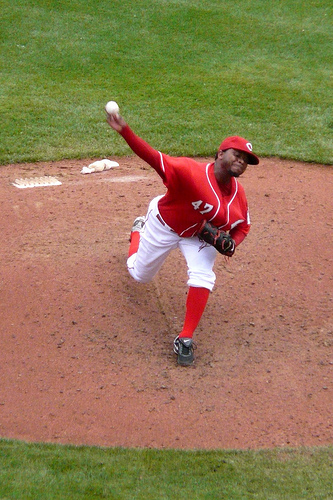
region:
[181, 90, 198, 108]
part of a grass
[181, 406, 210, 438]
part of a ground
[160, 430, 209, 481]
edge of a field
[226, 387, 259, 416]
part of a ground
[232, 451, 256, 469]
part of a fiedl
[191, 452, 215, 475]
part of a field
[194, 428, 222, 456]
part of a ground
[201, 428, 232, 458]
edge of a field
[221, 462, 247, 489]
part of a field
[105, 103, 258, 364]
A baseball player throwing a ball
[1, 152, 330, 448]
A pitcher's mound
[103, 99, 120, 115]
A baseball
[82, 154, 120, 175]
Some bags on the ground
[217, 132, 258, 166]
A red baseball cap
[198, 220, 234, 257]
A red and black baseball glove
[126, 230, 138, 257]
A red sock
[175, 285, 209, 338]
A red sock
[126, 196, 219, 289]
A pair of white pants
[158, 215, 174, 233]
A red cloth belt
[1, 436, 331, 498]
The grass is green.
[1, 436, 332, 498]
The grass is short.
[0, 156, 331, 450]
The dirt is brown.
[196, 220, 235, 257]
The person is wearing a mitt.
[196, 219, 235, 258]
The mitt is black.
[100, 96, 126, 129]
The person is holding a ball.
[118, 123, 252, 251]
The person is wearing a red top.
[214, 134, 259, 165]
The person is wearing a hat.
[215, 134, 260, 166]
The hat is red.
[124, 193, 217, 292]
The person is wearing white pants.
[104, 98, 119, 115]
White round baseball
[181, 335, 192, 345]
White Nike logo on shoe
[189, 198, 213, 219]
47 printed in white on red jersey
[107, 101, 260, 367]
Pitcher wearing red cap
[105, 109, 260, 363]
Pitcher wearing red jersey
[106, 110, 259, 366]
Pitcher wearing white pants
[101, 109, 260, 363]
Pitcher wearing red sock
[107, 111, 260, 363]
Pitcher carrying leather baseball glove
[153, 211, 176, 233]
Red belt on white pants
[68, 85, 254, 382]
The pitcher is throwing the ball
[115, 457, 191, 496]
The grass is on the outside of the field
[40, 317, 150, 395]
Stones on top of the dirt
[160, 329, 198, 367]
Cleat on the man's foot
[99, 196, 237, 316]
Player has short pants on with long socks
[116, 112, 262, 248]
The top that is worn is long sleeve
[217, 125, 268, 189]
The player is wearing a hat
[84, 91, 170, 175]
Pitcher has ball in hand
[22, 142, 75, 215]
Base sitting on the field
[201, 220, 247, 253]
Pitcher is wearing a glove